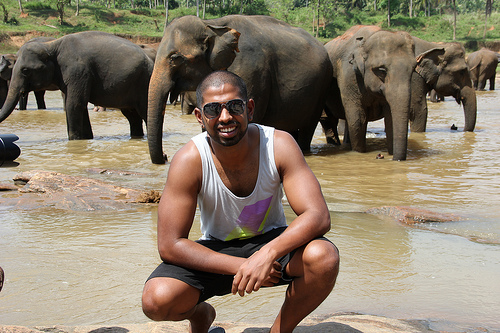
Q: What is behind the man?
A: Elephants.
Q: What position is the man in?
A: Kneeling.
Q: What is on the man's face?
A: Sunglasses.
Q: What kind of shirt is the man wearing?
A: Tank top.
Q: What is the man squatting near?
A: River edge.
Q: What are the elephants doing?
A: Wading.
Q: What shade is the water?
A: Brown.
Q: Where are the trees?
A: River bank.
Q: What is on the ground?
A: Sand.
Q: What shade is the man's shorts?
A: Black.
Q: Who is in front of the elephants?
A: Man in white tank top.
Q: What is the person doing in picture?
A: The man is squatting.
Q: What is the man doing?
A: Squatting.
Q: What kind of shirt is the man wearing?
A: A white tank top.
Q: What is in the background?
A: Elephants.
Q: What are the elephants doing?
A: Standing in water.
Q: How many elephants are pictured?
A: Six.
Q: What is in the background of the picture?
A: Elephants.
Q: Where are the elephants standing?
A: In water.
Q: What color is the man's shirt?
A: White.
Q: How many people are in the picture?
A: One.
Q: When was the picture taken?
A: Daytime.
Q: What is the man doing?
A: Crouching.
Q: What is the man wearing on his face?
A: Sunglasses.